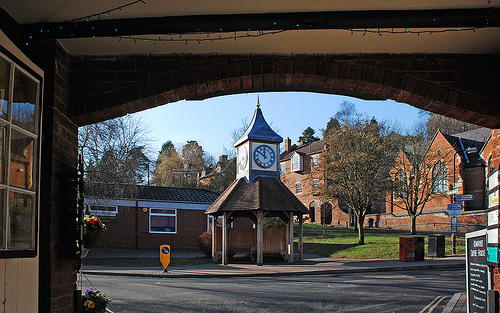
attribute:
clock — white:
[253, 138, 279, 172]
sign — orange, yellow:
[153, 238, 173, 274]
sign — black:
[458, 228, 500, 303]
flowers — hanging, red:
[81, 211, 107, 253]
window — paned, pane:
[4, 31, 55, 271]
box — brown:
[397, 224, 425, 262]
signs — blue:
[441, 183, 475, 253]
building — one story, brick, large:
[92, 178, 327, 271]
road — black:
[89, 261, 471, 310]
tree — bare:
[383, 149, 458, 250]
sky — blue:
[155, 103, 434, 143]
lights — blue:
[43, 15, 450, 47]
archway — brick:
[221, 202, 276, 273]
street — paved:
[106, 260, 416, 311]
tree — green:
[326, 125, 395, 260]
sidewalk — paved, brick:
[112, 246, 415, 271]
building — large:
[285, 137, 496, 234]